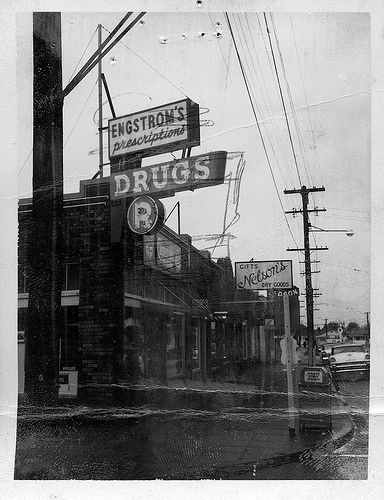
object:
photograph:
[1, 0, 383, 499]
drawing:
[182, 151, 254, 250]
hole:
[159, 37, 168, 45]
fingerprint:
[157, 418, 215, 477]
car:
[329, 343, 370, 381]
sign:
[107, 98, 199, 159]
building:
[16, 176, 204, 411]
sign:
[236, 259, 293, 289]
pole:
[284, 186, 326, 362]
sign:
[126, 195, 158, 235]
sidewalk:
[19, 355, 356, 479]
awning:
[144, 298, 213, 317]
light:
[345, 229, 354, 238]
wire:
[224, 8, 303, 248]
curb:
[177, 424, 339, 477]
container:
[301, 363, 331, 435]